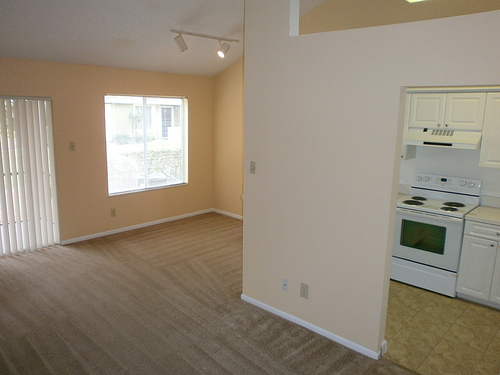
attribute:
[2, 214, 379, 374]
floor — brown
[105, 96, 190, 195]
window — glass, large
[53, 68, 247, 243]
wall — pale peach, tan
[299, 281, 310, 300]
electrical socket — off white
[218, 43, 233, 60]
ceiling light — lit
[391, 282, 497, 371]
floor — tiled, brown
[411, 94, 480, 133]
cabinet — white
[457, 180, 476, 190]
electric range — white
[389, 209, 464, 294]
oven — white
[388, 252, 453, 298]
oven hood — white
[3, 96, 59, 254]
blinds — white, long